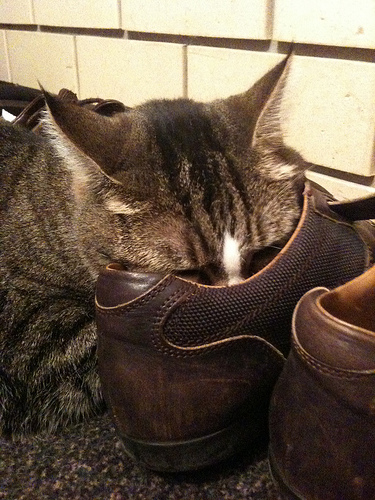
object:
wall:
[3, 0, 374, 210]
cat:
[5, 39, 309, 448]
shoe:
[91, 183, 374, 475]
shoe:
[263, 251, 373, 497]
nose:
[215, 277, 251, 291]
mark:
[219, 229, 245, 277]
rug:
[4, 411, 281, 499]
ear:
[36, 80, 121, 196]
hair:
[41, 112, 105, 188]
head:
[37, 39, 306, 304]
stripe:
[153, 108, 195, 222]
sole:
[117, 409, 270, 476]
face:
[143, 214, 298, 291]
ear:
[231, 38, 297, 165]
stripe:
[208, 122, 259, 236]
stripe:
[190, 214, 217, 262]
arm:
[3, 286, 109, 441]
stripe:
[7, 286, 84, 352]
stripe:
[28, 313, 92, 384]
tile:
[74, 31, 188, 113]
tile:
[187, 43, 374, 181]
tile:
[5, 28, 83, 101]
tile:
[120, 2, 274, 44]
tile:
[274, 2, 373, 56]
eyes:
[165, 237, 285, 280]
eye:
[169, 264, 217, 286]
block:
[1, 2, 37, 29]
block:
[32, 0, 123, 31]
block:
[294, 167, 374, 210]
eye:
[247, 239, 284, 275]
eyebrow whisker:
[254, 240, 288, 253]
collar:
[106, 180, 321, 313]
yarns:
[27, 436, 121, 481]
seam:
[146, 284, 231, 360]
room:
[1, 1, 373, 497]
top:
[288, 262, 374, 382]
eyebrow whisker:
[272, 153, 327, 201]